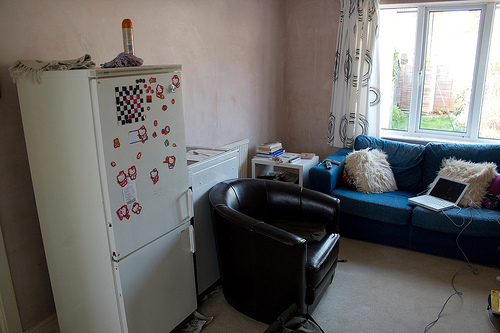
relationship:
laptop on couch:
[408, 175, 469, 212] [307, 135, 499, 271]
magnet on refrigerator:
[113, 203, 132, 221] [10, 62, 201, 332]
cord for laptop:
[423, 205, 482, 332] [408, 175, 469, 212]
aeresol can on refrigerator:
[122, 18, 135, 60] [10, 62, 201, 332]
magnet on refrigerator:
[130, 201, 145, 216] [10, 62, 201, 332]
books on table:
[255, 140, 288, 159] [250, 152, 321, 188]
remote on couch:
[323, 157, 343, 167] [307, 135, 499, 271]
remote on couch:
[324, 158, 333, 172] [307, 135, 499, 271]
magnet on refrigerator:
[117, 169, 129, 189] [10, 62, 201, 332]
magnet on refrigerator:
[128, 165, 139, 184] [10, 62, 201, 332]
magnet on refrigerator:
[148, 165, 163, 185] [10, 62, 201, 332]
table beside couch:
[250, 152, 321, 188] [307, 135, 499, 271]